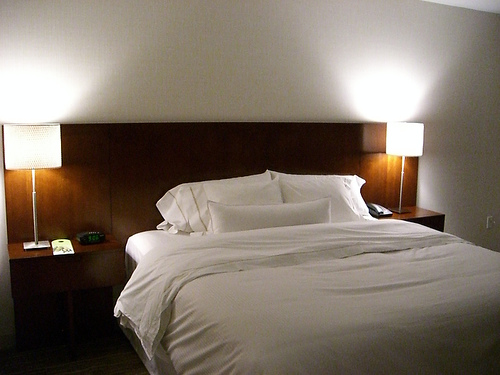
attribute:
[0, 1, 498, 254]
wall — white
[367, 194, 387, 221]
phone — silver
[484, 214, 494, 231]
socket — electrical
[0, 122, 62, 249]
lamp — Bright white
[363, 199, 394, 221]
phone — gray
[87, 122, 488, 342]
bed — wooden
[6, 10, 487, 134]
wall — white 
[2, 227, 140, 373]
desk — brown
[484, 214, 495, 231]
outlet — Small , white 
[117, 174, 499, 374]
bed — white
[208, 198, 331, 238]
pillow — white